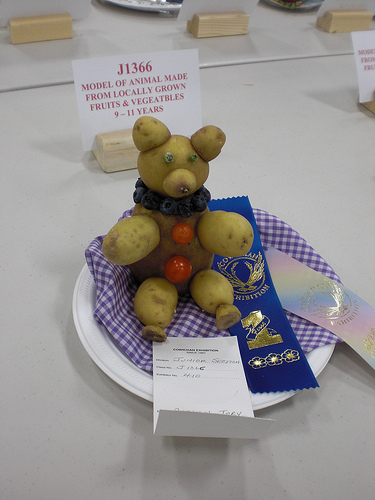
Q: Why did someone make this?
A: Competition.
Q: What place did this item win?
A: First place.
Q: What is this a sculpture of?
A: Bear.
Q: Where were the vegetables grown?
A: Locally.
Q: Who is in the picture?
A: No one.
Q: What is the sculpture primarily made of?
A: Potatoes.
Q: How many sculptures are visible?
A: One.